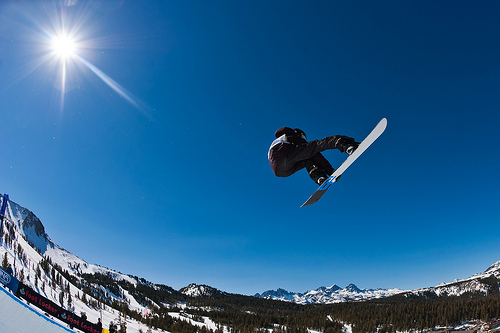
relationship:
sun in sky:
[36, 20, 91, 66] [3, 0, 498, 277]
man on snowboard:
[268, 127, 361, 186] [299, 114, 396, 210]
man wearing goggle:
[268, 127, 361, 186] [296, 128, 307, 140]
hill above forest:
[0, 193, 500, 333] [0, 219, 498, 329]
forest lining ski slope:
[0, 219, 500, 333] [0, 208, 142, 330]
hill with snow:
[0, 193, 500, 333] [303, 290, 405, 297]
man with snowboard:
[268, 127, 361, 186] [298, 115, 388, 210]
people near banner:
[78, 310, 85, 320] [1, 268, 105, 331]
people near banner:
[92, 315, 102, 324] [1, 268, 105, 331]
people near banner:
[108, 321, 118, 331] [1, 268, 105, 331]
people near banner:
[116, 321, 127, 331] [1, 268, 105, 331]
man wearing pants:
[226, 118, 347, 182] [273, 135, 355, 185]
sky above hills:
[183, 45, 310, 117] [243, 246, 383, 327]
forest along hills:
[0, 219, 500, 333] [3, 189, 474, 311]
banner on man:
[1, 268, 105, 331] [268, 127, 361, 186]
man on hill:
[268, 127, 361, 186] [4, 197, 194, 329]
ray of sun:
[10, 4, 175, 146] [0, 2, 148, 129]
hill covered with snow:
[1, 195, 182, 332] [1, 192, 233, 331]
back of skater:
[264, 132, 288, 169] [268, 130, 366, 183]